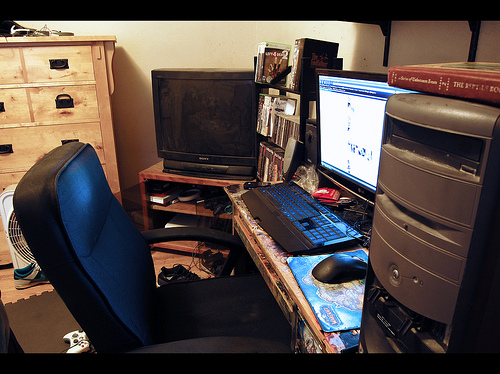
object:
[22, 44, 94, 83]
drawers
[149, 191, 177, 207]
games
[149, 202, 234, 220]
rack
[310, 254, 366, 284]
mouse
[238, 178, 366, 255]
keyboard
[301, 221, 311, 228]
keys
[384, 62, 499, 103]
book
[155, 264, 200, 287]
shoe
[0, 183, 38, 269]
fan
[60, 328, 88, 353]
control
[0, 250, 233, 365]
floor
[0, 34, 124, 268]
dresser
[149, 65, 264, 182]
television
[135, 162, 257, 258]
stand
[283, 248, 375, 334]
mouse pad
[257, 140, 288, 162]
shelves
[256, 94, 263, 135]
video games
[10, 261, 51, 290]
sneaker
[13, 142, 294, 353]
chair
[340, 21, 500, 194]
wall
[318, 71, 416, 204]
monitor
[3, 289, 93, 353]
mat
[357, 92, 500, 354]
computer tower